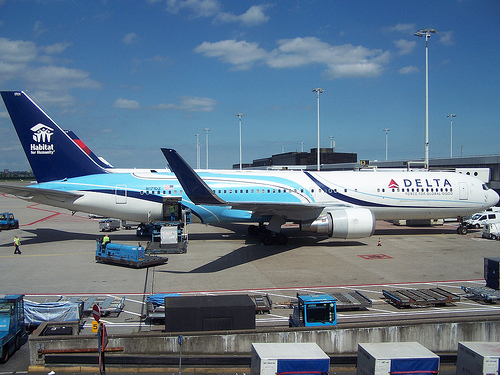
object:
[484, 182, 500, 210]
nose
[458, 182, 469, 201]
door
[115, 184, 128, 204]
door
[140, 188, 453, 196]
windows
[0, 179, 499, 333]
ground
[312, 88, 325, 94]
lights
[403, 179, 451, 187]
name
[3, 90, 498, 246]
blue/white plane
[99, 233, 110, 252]
employee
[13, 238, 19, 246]
shirt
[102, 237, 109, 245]
shirt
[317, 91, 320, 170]
pole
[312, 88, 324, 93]
light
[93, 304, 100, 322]
sign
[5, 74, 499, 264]
airplane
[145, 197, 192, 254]
ramp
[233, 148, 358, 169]
terminal roof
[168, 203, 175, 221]
people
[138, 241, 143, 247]
people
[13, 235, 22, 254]
person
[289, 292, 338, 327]
truck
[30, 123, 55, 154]
sign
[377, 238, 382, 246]
cone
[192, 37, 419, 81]
clouds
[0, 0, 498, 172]
sky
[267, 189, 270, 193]
window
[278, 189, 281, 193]
window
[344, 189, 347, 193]
window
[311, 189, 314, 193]
window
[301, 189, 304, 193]
window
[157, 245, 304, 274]
wing's shadow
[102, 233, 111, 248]
worker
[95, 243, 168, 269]
equipment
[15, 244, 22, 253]
pants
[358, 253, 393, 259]
tarmac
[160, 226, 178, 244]
supplies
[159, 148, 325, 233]
wing